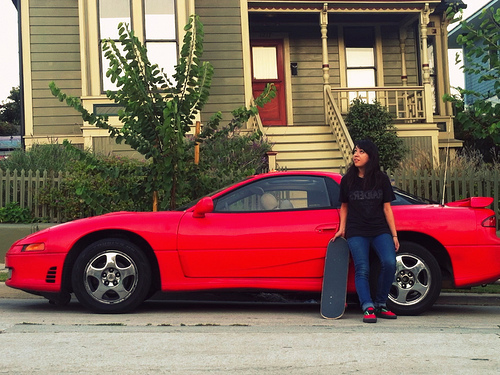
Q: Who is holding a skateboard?
A: Woman.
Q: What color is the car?
A: Red.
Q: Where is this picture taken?
A: Front of house.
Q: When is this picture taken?
A: Daytime.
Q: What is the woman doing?
A: Posing.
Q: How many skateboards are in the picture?
A: One.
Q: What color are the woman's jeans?
A: Blue.